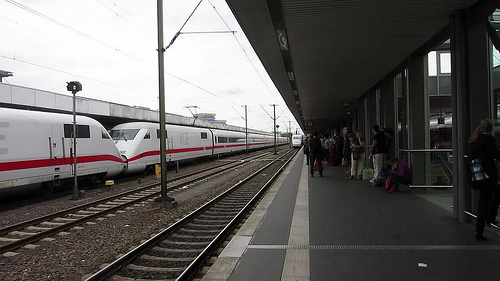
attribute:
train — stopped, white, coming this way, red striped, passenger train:
[290, 133, 303, 147]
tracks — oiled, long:
[82, 147, 298, 278]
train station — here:
[204, 1, 499, 280]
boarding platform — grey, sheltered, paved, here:
[202, 144, 497, 278]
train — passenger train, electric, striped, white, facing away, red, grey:
[1, 106, 124, 204]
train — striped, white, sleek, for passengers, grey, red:
[107, 122, 290, 177]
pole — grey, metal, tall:
[158, 0, 164, 200]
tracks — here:
[0, 144, 287, 256]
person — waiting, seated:
[387, 159, 411, 192]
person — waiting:
[309, 131, 324, 175]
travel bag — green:
[362, 168, 373, 182]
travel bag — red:
[384, 180, 393, 193]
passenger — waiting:
[369, 125, 387, 185]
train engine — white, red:
[109, 122, 212, 175]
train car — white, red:
[210, 128, 247, 158]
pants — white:
[372, 155, 383, 179]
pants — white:
[351, 152, 364, 177]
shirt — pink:
[396, 159, 411, 179]